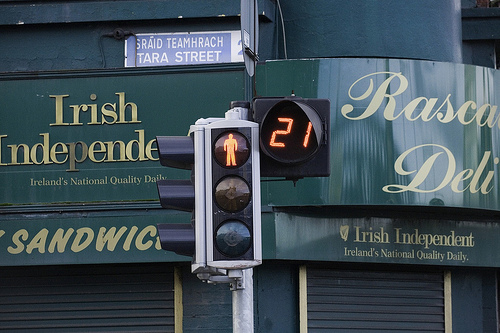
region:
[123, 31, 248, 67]
A blue and white street sign.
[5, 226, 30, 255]
The letter S on a sign.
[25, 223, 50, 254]
The letter A on a sign.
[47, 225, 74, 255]
The letter N on a sign.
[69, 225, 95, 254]
The letter D on a sign.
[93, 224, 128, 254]
The letter W on a sign.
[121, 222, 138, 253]
The letter I on a sign.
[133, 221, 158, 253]
The letter C on a sign.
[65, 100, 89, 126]
The letter R on a sign.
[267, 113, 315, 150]
The number 21 on a cross walk light.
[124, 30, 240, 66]
a blue street sign in Ireland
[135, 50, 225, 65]
"Tara Street" on the blue sign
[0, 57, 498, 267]
four green commercial signs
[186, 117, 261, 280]
a crosswalk sign with three lights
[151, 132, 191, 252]
a three light traffic sign on a metal pole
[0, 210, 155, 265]
a green sandwich shop commercial sign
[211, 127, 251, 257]
three crosswalk lights on a metal pole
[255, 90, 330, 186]
a black crosswalk timer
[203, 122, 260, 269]
crosswalk lights for predestrains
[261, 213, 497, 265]
a green "Irish Independent" commercial sign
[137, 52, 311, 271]
a traffic light on a pole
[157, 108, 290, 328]
a traffic light on a metal pole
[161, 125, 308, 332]
a pole with a traffic light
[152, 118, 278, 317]
a metal pole with a traffic light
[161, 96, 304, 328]
a light on a pole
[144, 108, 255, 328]
a light on a metal pole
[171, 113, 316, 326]
a pole with a light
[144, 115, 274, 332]
a metal pole with a light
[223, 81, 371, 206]
a timer on a sign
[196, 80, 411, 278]
a timer on a pole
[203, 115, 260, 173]
Man symbol on traffic light.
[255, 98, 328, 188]
Number twenty one on traffic signal.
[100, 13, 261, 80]
Blue and white street sign.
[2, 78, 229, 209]
Green and gold business sign.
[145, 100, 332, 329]
Traffic and crossing lights on pole.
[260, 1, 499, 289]
Corner sign in cursive.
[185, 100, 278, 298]
Three colored crossing light.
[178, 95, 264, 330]
Silver colored sign post.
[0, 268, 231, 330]
Green and gold window decor.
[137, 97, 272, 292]
Black traffic light covers.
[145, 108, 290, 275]
traffic light on a pole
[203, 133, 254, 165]
top traffic light lit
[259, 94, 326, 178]
traffic light displaying numbers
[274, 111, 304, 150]
number displayed on traffic light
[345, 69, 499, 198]
cursive lettering on building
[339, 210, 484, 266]
print lettering on building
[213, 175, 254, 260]
traffic lights that are not lit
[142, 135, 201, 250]
traffic lights not visible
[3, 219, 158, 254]
font different from lettering above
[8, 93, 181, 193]
font different from lettering below